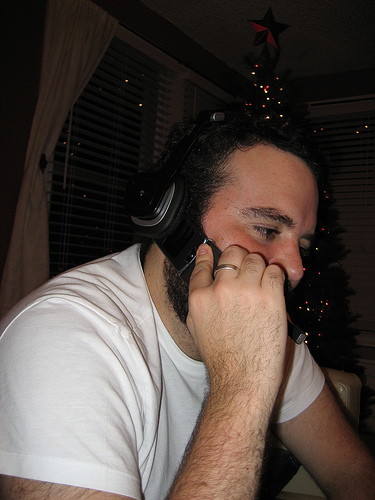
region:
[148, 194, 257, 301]
a man using a cell phone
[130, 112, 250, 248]
a man with head phones on his head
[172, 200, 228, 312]
a man holding a cell phone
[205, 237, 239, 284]
a man wearing a ring on his finger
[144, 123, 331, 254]
a man with black hair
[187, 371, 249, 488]
a man with hair on his arm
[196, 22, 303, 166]
a decorated christmas tree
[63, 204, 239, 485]
a man wearing a white shirt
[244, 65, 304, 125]
lights on a christmas tree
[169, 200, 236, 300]
a black flip cell phone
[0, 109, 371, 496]
a man wearing a head set while talking on a phone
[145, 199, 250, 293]
a black flip phone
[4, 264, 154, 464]
a white shirt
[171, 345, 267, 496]
a hairy arm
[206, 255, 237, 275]
a silver wedding ring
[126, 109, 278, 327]
a black head set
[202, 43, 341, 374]
a large christmas tree with some decorations on it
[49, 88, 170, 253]
some white window blinds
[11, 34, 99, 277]
some white window curtains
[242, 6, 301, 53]
a large red star on top of the christmas tree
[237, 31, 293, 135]
tree with christmas lights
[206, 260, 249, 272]
man's large silver ring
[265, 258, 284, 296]
man's knuckle with black hair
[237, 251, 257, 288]
man's knuckle with black hair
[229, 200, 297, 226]
man's thick black eyebrow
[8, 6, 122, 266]
sheer white panel curtain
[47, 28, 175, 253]
dark colored mini blinds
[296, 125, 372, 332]
light colored mini blinds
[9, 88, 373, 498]
man listening to headphones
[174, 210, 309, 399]
man's hand holding microphone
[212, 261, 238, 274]
Wedding Ring on finger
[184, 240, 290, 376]
Hand of person talking on phone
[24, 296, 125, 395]
Shoulder of person talking on phone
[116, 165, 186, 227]
Part of headphone of talking person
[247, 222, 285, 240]
Eye of talking perdson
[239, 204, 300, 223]
Eyebrow of talking person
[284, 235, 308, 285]
Part of talking person's nose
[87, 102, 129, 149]
Part of white miniblinds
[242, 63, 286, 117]
Part of christmas tree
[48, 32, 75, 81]
Part of drapes on window